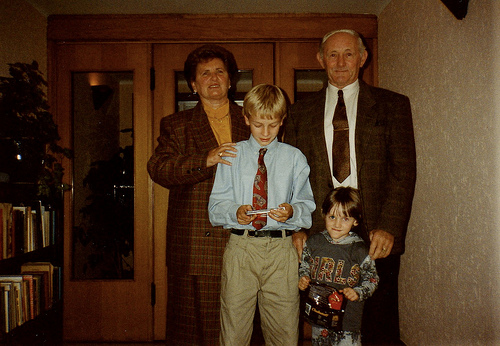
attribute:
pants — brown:
[218, 227, 299, 344]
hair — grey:
[312, 24, 366, 64]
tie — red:
[249, 145, 272, 231]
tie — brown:
[305, 89, 373, 211]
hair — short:
[316, 22, 378, 58]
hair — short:
[331, 190, 378, 231]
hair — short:
[246, 74, 288, 133]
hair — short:
[173, 41, 244, 96]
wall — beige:
[421, 73, 469, 222]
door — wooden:
[55, 42, 151, 344]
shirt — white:
[306, 74, 437, 218]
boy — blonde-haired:
[209, 83, 313, 344]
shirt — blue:
[213, 137, 311, 228]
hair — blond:
[331, 191, 354, 205]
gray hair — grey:
[319, 27, 364, 57]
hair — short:
[320, 185, 364, 224]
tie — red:
[251, 148, 268, 229]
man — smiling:
[309, 35, 454, 247]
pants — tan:
[214, 222, 305, 343]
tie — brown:
[331, 89, 351, 184]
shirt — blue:
[264, 159, 299, 211]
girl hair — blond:
[313, 187, 371, 252]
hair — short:
[175, 42, 244, 92]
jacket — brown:
[302, 85, 419, 248]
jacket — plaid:
[146, 85, 216, 343]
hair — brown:
[182, 38, 241, 92]